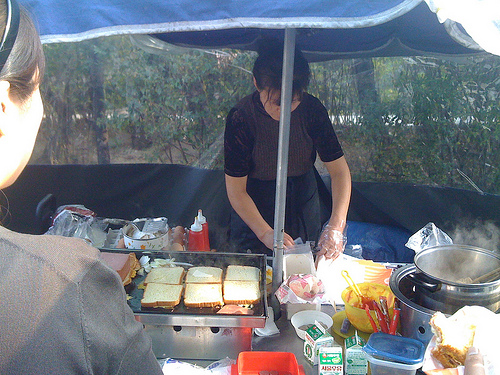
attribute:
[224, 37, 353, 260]
woman — cooking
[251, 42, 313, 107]
hair — brown, black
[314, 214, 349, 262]
glove — clear, nylon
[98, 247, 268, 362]
grill — stainless steel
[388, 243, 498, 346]
pot — steaming, cooking, metal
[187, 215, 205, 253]
ketchup bottle — red, white, plastic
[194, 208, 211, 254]
ketchup bottle — red, white, plastic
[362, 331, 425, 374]
tupperware — plastic, small, clear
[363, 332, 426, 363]
lid — blue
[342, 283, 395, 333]
bowl — small, yellow, orange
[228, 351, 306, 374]
container — red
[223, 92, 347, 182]
blouse — black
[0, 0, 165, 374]
woman — customer, waiting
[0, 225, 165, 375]
shirt — grey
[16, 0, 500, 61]
tent — blue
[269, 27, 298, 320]
pole — grey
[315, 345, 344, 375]
container — little, green, cardboard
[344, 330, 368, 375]
container — little, green, cardboard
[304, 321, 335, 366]
container — little, green, cardboard